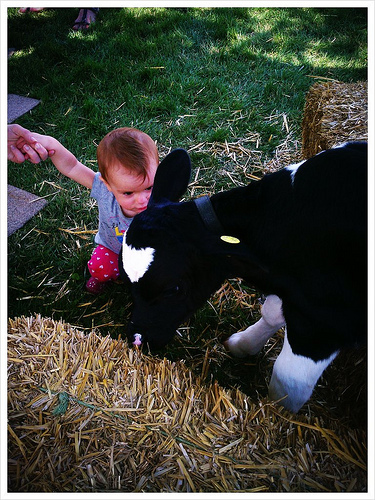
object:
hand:
[7, 123, 49, 164]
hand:
[16, 132, 42, 160]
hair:
[96, 127, 159, 187]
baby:
[16, 127, 160, 295]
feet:
[72, 8, 99, 30]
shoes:
[86, 277, 124, 294]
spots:
[315, 141, 349, 156]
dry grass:
[7, 311, 368, 493]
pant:
[16, 126, 159, 294]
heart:
[100, 247, 104, 250]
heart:
[105, 252, 109, 256]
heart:
[110, 260, 113, 264]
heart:
[99, 265, 103, 269]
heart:
[104, 274, 109, 277]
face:
[117, 208, 183, 355]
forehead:
[118, 210, 169, 294]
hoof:
[224, 331, 248, 359]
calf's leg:
[244, 294, 286, 356]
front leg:
[268, 298, 346, 414]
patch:
[121, 226, 155, 283]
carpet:
[7, 184, 49, 238]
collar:
[194, 195, 235, 260]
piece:
[50, 391, 69, 417]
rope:
[38, 386, 281, 481]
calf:
[117, 138, 368, 416]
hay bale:
[7, 313, 367, 493]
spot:
[282, 159, 308, 188]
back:
[293, 206, 365, 270]